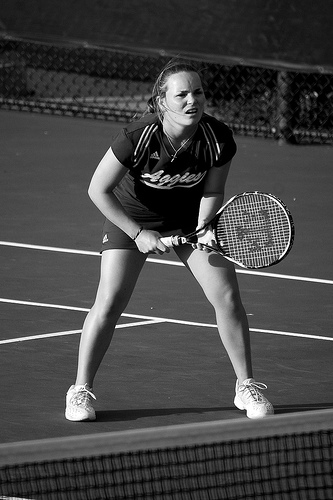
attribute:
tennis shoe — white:
[64, 384, 95, 425]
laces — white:
[235, 380, 267, 401]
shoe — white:
[232, 376, 274, 419]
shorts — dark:
[100, 201, 231, 250]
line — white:
[0, 319, 161, 361]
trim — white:
[1, 411, 329, 461]